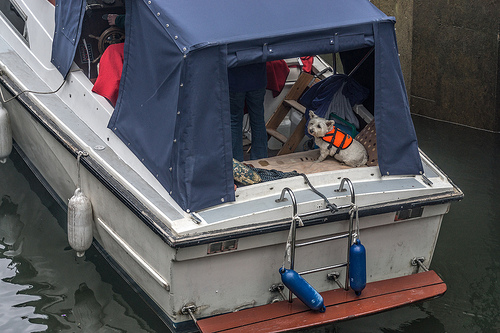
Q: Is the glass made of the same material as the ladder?
A: No, the glass is made of glass and the ladder is made of wood.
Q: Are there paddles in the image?
A: No, there are no paddles.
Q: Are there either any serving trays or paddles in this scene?
A: No, there are no paddles or serving trays.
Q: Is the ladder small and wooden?
A: Yes, the ladder is small and wooden.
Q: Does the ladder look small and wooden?
A: Yes, the ladder is small and wooden.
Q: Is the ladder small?
A: Yes, the ladder is small.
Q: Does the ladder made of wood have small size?
A: Yes, the ladder is small.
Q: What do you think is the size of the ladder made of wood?
A: The ladder is small.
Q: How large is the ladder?
A: The ladder is small.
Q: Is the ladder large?
A: No, the ladder is small.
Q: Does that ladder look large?
A: No, the ladder is small.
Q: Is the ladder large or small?
A: The ladder is small.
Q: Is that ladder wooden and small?
A: Yes, the ladder is wooden and small.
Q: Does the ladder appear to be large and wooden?
A: No, the ladder is wooden but small.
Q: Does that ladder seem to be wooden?
A: Yes, the ladder is wooden.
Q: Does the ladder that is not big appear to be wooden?
A: Yes, the ladder is wooden.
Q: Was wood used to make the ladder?
A: Yes, the ladder is made of wood.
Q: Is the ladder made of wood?
A: Yes, the ladder is made of wood.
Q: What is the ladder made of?
A: The ladder is made of wood.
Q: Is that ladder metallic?
A: No, the ladder is wooden.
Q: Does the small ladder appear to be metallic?
A: No, the ladder is wooden.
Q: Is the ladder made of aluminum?
A: No, the ladder is made of wood.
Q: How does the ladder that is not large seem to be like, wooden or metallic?
A: The ladder is wooden.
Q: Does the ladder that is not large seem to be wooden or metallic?
A: The ladder is wooden.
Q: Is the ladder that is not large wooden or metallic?
A: The ladder is wooden.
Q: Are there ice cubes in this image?
A: No, there are no ice cubes.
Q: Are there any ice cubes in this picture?
A: No, there are no ice cubes.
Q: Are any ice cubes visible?
A: No, there are no ice cubes.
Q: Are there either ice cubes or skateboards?
A: No, there are no ice cubes or skateboards.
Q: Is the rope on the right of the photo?
A: Yes, the rope is on the right of the image.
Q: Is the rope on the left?
A: No, the rope is on the right of the image.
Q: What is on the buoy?
A: The rope is on the buoy.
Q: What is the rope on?
A: The rope is on the buoy.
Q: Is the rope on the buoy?
A: Yes, the rope is on the buoy.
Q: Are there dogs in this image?
A: Yes, there is a dog.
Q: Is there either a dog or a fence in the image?
A: Yes, there is a dog.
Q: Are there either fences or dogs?
A: Yes, there is a dog.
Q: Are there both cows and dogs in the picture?
A: No, there is a dog but no cows.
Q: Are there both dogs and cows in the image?
A: No, there is a dog but no cows.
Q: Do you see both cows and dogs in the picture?
A: No, there is a dog but no cows.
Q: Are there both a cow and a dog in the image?
A: No, there is a dog but no cows.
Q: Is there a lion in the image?
A: No, there are no lions.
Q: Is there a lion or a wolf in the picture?
A: No, there are no lions or wolves.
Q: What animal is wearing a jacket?
A: The dog is wearing a jacket.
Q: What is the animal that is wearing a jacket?
A: The animal is a dog.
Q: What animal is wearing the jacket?
A: The animal is a dog.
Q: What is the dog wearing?
A: The dog is wearing a jacket.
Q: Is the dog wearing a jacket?
A: Yes, the dog is wearing a jacket.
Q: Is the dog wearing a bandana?
A: No, the dog is wearing a jacket.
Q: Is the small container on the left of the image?
A: Yes, the container is on the left of the image.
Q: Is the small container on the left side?
A: Yes, the container is on the left of the image.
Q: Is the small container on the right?
A: No, the container is on the left of the image.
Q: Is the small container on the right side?
A: No, the container is on the left of the image.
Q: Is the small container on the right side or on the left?
A: The container is on the left of the image.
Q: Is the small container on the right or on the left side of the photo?
A: The container is on the left of the image.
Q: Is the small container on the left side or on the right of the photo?
A: The container is on the left of the image.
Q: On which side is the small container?
A: The container is on the left of the image.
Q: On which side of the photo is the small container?
A: The container is on the left of the image.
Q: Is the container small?
A: Yes, the container is small.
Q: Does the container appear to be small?
A: Yes, the container is small.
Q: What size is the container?
A: The container is small.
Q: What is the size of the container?
A: The container is small.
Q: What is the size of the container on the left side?
A: The container is small.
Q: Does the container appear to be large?
A: No, the container is small.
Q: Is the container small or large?
A: The container is small.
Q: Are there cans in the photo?
A: No, there are no cans.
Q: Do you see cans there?
A: No, there are no cans.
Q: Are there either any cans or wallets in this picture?
A: No, there are no cans or wallets.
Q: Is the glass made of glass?
A: Yes, the glass is made of glass.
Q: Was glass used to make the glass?
A: Yes, the glass is made of glass.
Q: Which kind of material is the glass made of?
A: The glass is made of glass.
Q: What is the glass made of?
A: The glass is made of glass.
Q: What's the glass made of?
A: The glass is made of glass.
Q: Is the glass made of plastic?
A: No, the glass is made of glass.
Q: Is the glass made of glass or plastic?
A: The glass is made of glass.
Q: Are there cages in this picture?
A: No, there are no cages.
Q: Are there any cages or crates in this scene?
A: No, there are no cages or crates.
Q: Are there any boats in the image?
A: Yes, there is a boat.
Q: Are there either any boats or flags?
A: Yes, there is a boat.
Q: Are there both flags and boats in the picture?
A: No, there is a boat but no flags.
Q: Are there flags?
A: No, there are no flags.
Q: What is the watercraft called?
A: The watercraft is a boat.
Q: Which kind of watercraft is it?
A: The watercraft is a boat.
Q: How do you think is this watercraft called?
A: This is a boat.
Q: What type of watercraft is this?
A: This is a boat.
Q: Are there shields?
A: No, there are no shields.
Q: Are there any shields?
A: No, there are no shields.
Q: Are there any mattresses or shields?
A: No, there are no shields or mattresses.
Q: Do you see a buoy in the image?
A: Yes, there is a buoy.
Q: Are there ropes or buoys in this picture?
A: Yes, there is a buoy.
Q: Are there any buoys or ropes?
A: Yes, there is a buoy.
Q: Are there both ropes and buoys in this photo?
A: Yes, there are both a buoy and a rope.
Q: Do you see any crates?
A: No, there are no crates.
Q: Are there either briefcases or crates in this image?
A: No, there are no crates or briefcases.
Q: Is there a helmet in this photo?
A: No, there are no helmets.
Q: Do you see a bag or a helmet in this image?
A: No, there are no helmets or bags.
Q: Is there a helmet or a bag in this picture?
A: No, there are no helmets or bags.